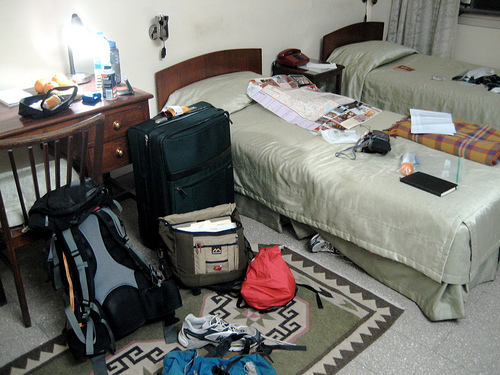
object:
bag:
[241, 246, 299, 311]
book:
[399, 170, 459, 197]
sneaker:
[179, 314, 261, 350]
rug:
[1, 243, 405, 375]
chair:
[1, 111, 107, 329]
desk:
[0, 74, 155, 330]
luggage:
[129, 101, 234, 251]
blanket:
[383, 110, 499, 165]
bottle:
[95, 57, 103, 89]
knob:
[113, 120, 122, 131]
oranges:
[34, 70, 73, 92]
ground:
[1, 188, 498, 374]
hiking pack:
[24, 180, 182, 365]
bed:
[155, 22, 499, 292]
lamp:
[67, 13, 90, 84]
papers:
[408, 107, 457, 138]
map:
[245, 75, 382, 134]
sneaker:
[309, 233, 341, 255]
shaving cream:
[99, 66, 120, 100]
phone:
[277, 48, 312, 67]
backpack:
[162, 348, 275, 374]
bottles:
[101, 65, 118, 101]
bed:
[322, 19, 499, 130]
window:
[458, 0, 498, 23]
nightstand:
[272, 59, 345, 95]